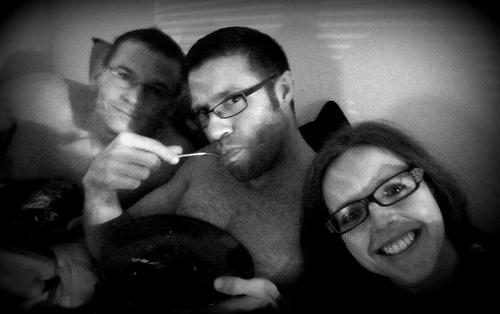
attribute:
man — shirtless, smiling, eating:
[82, 26, 319, 311]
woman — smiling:
[300, 121, 498, 313]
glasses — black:
[325, 160, 424, 236]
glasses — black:
[185, 72, 281, 131]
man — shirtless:
[1, 26, 197, 250]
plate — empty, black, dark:
[95, 214, 255, 309]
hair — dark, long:
[303, 119, 472, 284]